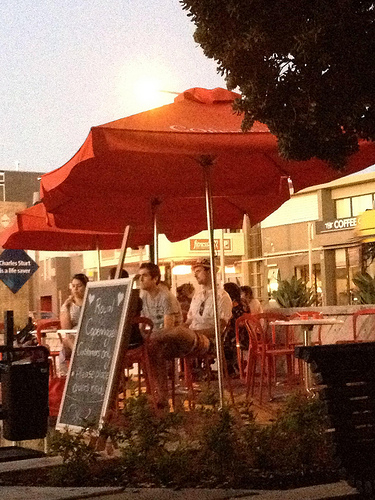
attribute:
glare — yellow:
[104, 46, 173, 110]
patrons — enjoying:
[36, 249, 268, 386]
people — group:
[176, 274, 267, 332]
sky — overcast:
[0, 34, 81, 111]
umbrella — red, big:
[34, 75, 368, 235]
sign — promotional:
[0, 247, 63, 294]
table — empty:
[270, 313, 342, 401]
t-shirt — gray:
[141, 289, 182, 327]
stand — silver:
[194, 157, 229, 421]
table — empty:
[233, 287, 374, 362]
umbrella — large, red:
[45, 76, 373, 227]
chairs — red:
[237, 307, 373, 405]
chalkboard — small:
[46, 260, 147, 446]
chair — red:
[250, 307, 353, 399]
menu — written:
[60, 275, 122, 448]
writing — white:
[0, 256, 40, 276]